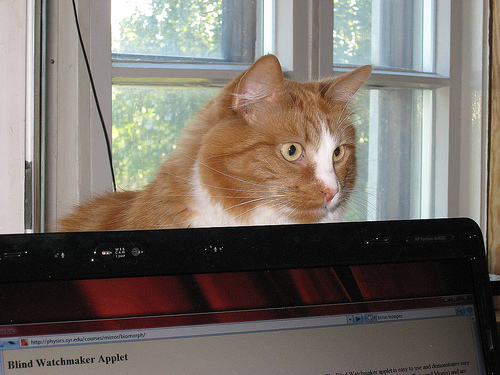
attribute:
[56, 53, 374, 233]
cat — orange, white, tan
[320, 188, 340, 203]
nose — pink, little, white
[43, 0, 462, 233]
window — white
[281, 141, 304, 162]
eye — yellow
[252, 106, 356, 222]
face — orange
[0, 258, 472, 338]
border — red, black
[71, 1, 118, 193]
wire — black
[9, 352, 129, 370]
words — black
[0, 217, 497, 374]
computer — open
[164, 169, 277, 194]
whisker — long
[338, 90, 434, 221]
window pane — lower right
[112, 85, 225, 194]
window pane — lower left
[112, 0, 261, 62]
window pane — upper left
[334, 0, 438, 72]
window pane — upper right